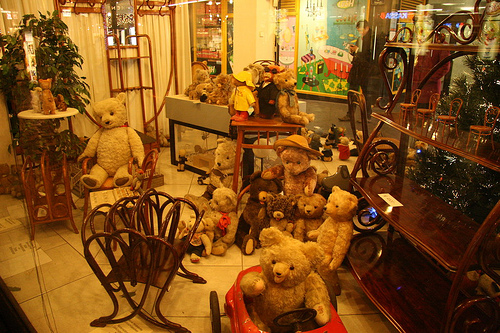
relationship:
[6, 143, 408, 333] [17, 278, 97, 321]
floor on ground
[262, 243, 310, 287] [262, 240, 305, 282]
face on face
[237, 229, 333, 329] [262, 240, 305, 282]
bear has face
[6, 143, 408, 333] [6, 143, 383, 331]
floor on floor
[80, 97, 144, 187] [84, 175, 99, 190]
bear has paw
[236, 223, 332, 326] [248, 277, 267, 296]
stuffed bear has bear paw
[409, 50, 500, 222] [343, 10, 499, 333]
christmas tree showing through shelf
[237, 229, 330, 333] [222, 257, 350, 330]
bear in red car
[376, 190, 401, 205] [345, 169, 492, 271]
paper on shelf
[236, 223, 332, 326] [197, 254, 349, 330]
stuffed bear in car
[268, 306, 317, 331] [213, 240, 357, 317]
steering wheel in front of bear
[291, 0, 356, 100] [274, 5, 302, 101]
painting on wall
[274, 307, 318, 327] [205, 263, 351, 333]
steering wheel of red car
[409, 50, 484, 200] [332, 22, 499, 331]
christmas tree behind shelf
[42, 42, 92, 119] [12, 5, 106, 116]
green leaves on plant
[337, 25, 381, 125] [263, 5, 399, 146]
man standing outside store window